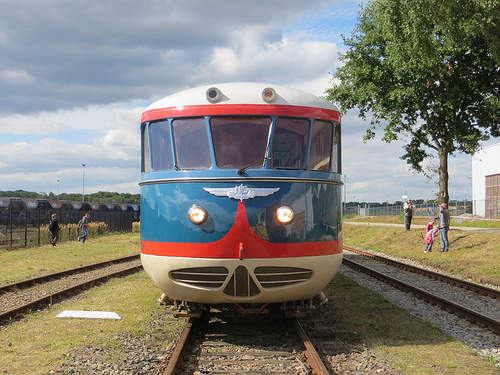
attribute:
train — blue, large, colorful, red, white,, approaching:
[140, 82, 345, 322]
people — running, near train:
[46, 193, 453, 255]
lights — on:
[189, 203, 296, 226]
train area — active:
[0, 84, 499, 375]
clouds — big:
[0, 1, 499, 197]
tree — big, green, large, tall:
[331, 3, 500, 230]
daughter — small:
[421, 221, 435, 254]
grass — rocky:
[5, 250, 500, 374]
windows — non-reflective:
[138, 120, 340, 173]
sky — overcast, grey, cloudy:
[0, 1, 315, 80]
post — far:
[78, 162, 87, 204]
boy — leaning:
[47, 210, 60, 245]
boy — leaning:
[75, 211, 91, 247]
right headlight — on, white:
[276, 204, 298, 227]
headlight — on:
[189, 206, 209, 225]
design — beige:
[150, 256, 321, 306]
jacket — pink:
[426, 229, 435, 243]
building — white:
[468, 140, 499, 222]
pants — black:
[404, 214, 412, 231]